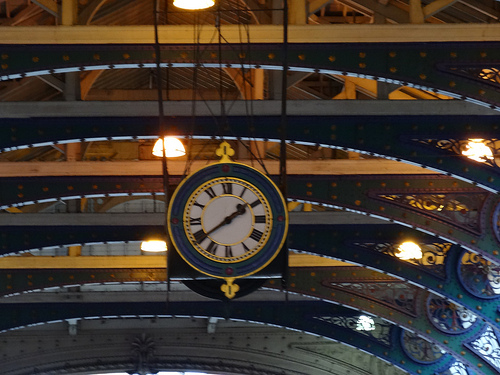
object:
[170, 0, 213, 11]
light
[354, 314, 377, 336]
light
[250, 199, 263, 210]
number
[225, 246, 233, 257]
number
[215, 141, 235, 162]
decoration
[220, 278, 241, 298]
decoration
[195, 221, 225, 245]
hand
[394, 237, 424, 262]
light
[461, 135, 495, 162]
light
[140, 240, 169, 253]
ceiling light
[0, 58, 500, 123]
arch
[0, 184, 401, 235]
arch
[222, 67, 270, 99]
wood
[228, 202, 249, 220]
hand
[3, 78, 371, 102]
ceiling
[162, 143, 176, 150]
light bulb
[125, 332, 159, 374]
artwork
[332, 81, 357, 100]
ceiling supports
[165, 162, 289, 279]
clock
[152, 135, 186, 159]
light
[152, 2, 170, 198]
hanger rod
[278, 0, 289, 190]
hanger rod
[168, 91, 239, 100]
decorative bands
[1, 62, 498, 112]
sky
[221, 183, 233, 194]
numeral 12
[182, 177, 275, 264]
clock face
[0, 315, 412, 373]
entrance arch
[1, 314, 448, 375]
arch supports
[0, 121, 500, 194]
arch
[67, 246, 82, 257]
ceiling supports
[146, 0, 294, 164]
frame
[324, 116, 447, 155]
frame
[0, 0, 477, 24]
ceiling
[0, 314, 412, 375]
support